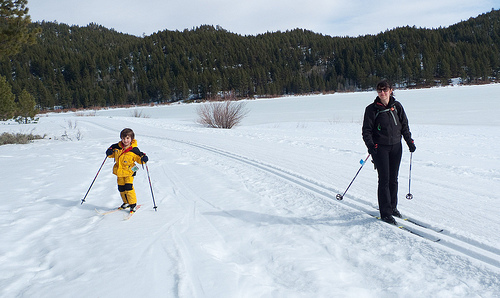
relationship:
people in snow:
[95, 77, 421, 220] [183, 227, 385, 290]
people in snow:
[95, 77, 421, 220] [181, 241, 382, 290]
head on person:
[371, 74, 392, 100] [363, 80, 419, 230]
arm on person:
[361, 104, 380, 148] [357, 80, 419, 226]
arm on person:
[393, 94, 416, 152] [357, 80, 419, 226]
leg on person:
[375, 156, 396, 223] [357, 80, 419, 226]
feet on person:
[375, 210, 399, 228] [359, 74, 421, 230]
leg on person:
[383, 144, 408, 224] [359, 74, 421, 230]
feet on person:
[386, 202, 404, 217] [357, 80, 419, 226]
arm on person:
[99, 133, 121, 162] [101, 116, 148, 216]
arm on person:
[133, 144, 153, 165] [102, 117, 152, 212]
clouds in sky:
[321, 7, 471, 44] [4, 2, 498, 40]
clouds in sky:
[121, 4, 175, 26] [6, 1, 496, 48]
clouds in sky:
[218, 2, 351, 42] [4, 2, 498, 52]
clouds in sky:
[403, 12, 479, 37] [6, 1, 496, 48]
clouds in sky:
[99, 3, 165, 33] [4, 2, 498, 40]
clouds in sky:
[80, 3, 123, 23] [4, 2, 498, 40]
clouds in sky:
[24, 3, 66, 24] [6, 1, 496, 48]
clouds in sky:
[343, 13, 380, 37] [1, 2, 498, 34]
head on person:
[375, 81, 393, 100] [359, 74, 421, 230]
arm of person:
[341, 98, 381, 184] [313, 63, 473, 273]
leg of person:
[107, 160, 159, 211] [304, 62, 445, 259]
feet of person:
[375, 210, 399, 228] [74, 98, 174, 249]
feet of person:
[386, 202, 404, 217] [318, 54, 452, 264]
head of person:
[375, 81, 393, 100] [314, 56, 457, 275]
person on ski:
[325, 52, 452, 292] [318, 130, 389, 243]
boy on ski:
[104, 128, 147, 212] [320, 133, 383, 242]